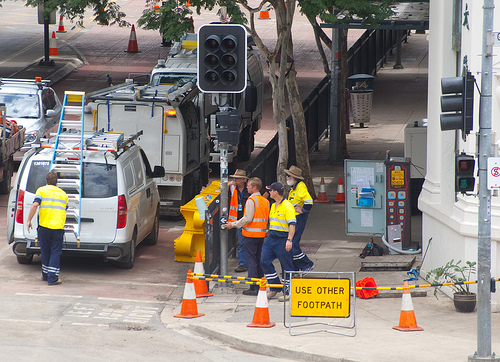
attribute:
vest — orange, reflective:
[221, 193, 269, 243]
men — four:
[280, 165, 313, 268]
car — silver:
[0, 76, 64, 161]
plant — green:
[424, 257, 474, 292]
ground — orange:
[393, 135, 428, 177]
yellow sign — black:
[280, 274, 355, 328]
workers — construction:
[230, 161, 319, 300]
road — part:
[81, 297, 151, 360]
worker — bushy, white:
[278, 163, 307, 188]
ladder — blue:
[44, 88, 83, 235]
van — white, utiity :
[31, 131, 219, 265]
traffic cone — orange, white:
[389, 276, 428, 338]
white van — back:
[15, 164, 125, 251]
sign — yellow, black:
[291, 278, 351, 318]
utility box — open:
[341, 157, 411, 247]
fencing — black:
[236, 21, 416, 173]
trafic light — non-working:
[193, 18, 251, 98]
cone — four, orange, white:
[179, 269, 199, 322]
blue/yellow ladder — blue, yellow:
[45, 85, 89, 245]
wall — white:
[427, 0, 449, 204]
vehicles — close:
[7, 38, 263, 263]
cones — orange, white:
[138, 253, 409, 334]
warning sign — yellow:
[287, 269, 359, 322]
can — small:
[345, 70, 377, 128]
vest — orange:
[226, 175, 271, 247]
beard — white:
[282, 173, 302, 187]